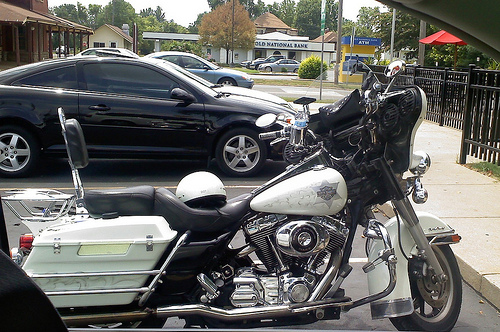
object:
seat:
[57, 113, 254, 228]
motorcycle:
[10, 62, 471, 325]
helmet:
[170, 168, 230, 213]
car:
[2, 54, 291, 176]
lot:
[2, 42, 492, 326]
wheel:
[214, 127, 271, 179]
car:
[139, 50, 258, 87]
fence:
[366, 59, 499, 168]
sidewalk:
[425, 84, 499, 300]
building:
[0, 1, 55, 66]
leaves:
[197, 3, 258, 50]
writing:
[253, 37, 383, 50]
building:
[145, 20, 335, 77]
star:
[313, 177, 344, 209]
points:
[311, 177, 348, 214]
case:
[14, 215, 174, 292]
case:
[315, 88, 363, 132]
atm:
[337, 35, 382, 87]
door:
[78, 60, 204, 163]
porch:
[2, 23, 92, 71]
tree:
[192, 1, 258, 65]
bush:
[297, 55, 329, 81]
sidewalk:
[255, 71, 302, 83]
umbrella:
[417, 26, 466, 49]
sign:
[316, 1, 331, 40]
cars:
[256, 57, 309, 74]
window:
[81, 58, 181, 99]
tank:
[251, 164, 347, 215]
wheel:
[383, 215, 464, 331]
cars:
[137, 49, 256, 92]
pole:
[318, 30, 327, 107]